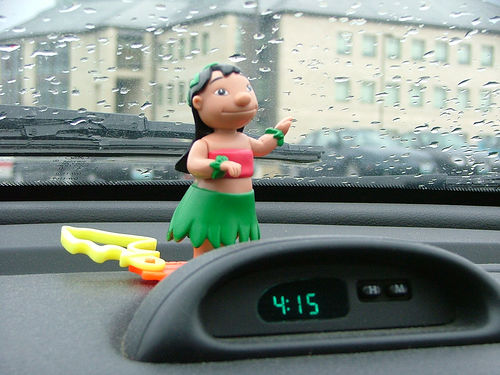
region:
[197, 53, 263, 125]
head of a figure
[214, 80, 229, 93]
eye of a figure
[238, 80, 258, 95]
eye of a figure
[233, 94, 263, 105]
nose of a figure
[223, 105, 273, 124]
smile of a figure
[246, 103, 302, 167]
arm of a figure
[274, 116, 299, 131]
hand of a figure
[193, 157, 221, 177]
arm of a figure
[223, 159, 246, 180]
hand of a figure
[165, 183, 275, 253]
grass dress of a figure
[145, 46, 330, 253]
this is a doll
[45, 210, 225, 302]
this is a toy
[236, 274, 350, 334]
this is a clock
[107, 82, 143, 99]
this is a drop of water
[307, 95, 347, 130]
this is a drop of water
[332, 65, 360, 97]
this is a drop of water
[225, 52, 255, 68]
this is a drop of water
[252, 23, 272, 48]
this is a drop of water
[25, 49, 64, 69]
this is a drop of water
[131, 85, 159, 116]
this is a drop of water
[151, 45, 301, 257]
a small toy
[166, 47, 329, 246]
a small Lilo toy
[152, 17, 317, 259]
a small toy from Lilo and Stitch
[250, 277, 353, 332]
a digital clock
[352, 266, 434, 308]
buttons to change the time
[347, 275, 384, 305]
this button is for the hour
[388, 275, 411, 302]
this button is for the minute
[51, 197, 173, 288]
this is a keychain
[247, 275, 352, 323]
the clock reads 4:15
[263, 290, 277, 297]
Clock with the time on the front.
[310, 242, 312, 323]
Clock with the time on the front.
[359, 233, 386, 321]
Clock with the time on the front.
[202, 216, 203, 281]
Clock with the time on the front.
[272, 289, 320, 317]
The time is 4:15.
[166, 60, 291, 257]
A Lilo bobblehead is sitting on the dashboard.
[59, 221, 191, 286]
A yellow and orange toy is sitting on the dashboard.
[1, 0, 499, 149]
A large building can be seen outside.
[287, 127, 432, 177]
A black car is parked outside.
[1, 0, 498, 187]
It is raining outside.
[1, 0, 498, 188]
The windshield has many raindrops on it.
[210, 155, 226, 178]
Lilo is wearing a green wristband.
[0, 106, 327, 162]
The windshield wipers are down.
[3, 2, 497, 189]
Raindrops on windshield of car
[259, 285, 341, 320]
Digital clock in car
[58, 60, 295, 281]
Decorative hula girl on inside of car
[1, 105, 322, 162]
Windshield wiper on window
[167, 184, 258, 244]
Hula skirt on girl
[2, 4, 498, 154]
Buildings in front of car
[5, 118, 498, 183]
Cars parked in front of building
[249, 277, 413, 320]
Digital clock and buttons to set time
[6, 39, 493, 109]
Windows on buildings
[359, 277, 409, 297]
Buttons for setting hours and minutes on clock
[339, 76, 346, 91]
a window on the building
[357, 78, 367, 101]
a window on the building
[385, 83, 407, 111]
a window on the building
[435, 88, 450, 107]
a window on the building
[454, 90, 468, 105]
a window on the building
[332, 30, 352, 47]
a window on the building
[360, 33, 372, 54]
a window on the building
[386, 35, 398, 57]
a window on the building